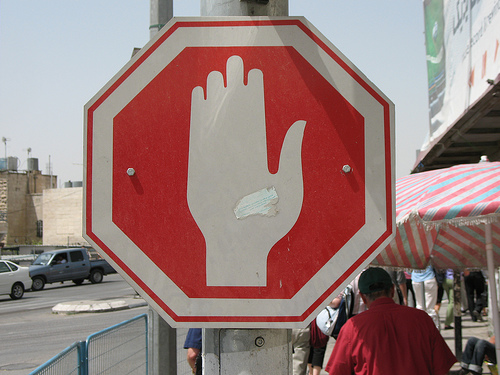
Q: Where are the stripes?
A: Awning.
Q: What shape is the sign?
A: Octagon.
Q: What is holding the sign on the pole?
A: Metal bolts.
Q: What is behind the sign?
A: A man.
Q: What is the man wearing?
A: A red shirt.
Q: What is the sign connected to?
A: Metal pole.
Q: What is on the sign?
A: A hand.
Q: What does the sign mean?
A: Stop.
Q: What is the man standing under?
A: An umbrella.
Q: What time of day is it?
A: Afternoon.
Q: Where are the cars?
A: In the parking lot.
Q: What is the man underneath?
A: An umbrella.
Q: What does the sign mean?
A: Stop.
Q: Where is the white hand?
A: On a stop sign.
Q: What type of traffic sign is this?
A: A stop sign.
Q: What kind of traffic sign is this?
A: A stop sign.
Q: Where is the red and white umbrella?
A: Behind the stop sign.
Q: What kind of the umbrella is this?
A: A canopy umbrella.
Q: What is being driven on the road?
A: Cars.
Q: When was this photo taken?
A: During the day.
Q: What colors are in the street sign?
A: Red and white.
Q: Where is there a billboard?
A: Upper right corner.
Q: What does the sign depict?
A: A hand.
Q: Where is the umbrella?
A: Behind the street sign.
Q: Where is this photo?
A: City street.